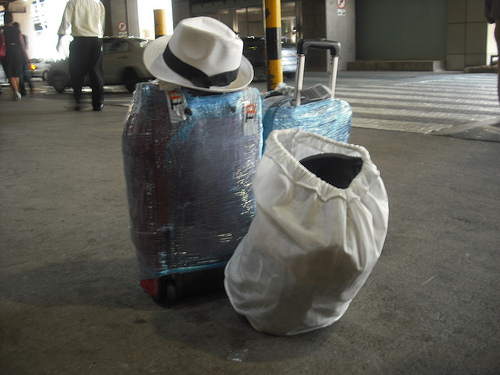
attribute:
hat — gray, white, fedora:
[139, 8, 254, 103]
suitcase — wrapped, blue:
[118, 71, 261, 343]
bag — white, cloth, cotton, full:
[247, 130, 387, 351]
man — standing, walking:
[54, 2, 120, 119]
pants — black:
[65, 37, 109, 112]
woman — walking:
[0, 15, 34, 103]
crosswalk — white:
[380, 68, 499, 138]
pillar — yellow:
[258, 0, 284, 92]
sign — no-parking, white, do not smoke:
[336, 2, 348, 13]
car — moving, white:
[48, 36, 148, 102]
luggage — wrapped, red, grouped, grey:
[257, 66, 361, 142]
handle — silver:
[290, 32, 347, 114]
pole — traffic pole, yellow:
[262, 11, 285, 87]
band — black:
[164, 49, 235, 95]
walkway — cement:
[7, 107, 133, 352]